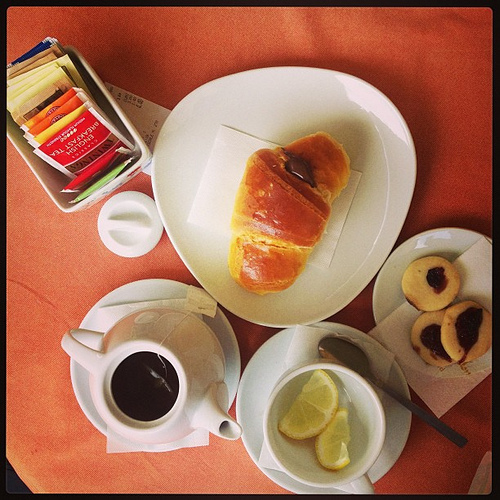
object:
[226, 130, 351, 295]
crossant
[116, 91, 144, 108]
black lettering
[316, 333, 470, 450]
metal spoon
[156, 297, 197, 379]
bag string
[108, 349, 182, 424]
brewed drink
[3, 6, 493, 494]
ground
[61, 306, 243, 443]
kettle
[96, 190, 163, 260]
top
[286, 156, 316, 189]
chocolate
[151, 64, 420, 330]
plate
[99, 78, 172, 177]
bill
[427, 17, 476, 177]
table cloth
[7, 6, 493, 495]
table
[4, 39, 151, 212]
container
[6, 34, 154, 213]
bags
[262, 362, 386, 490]
bowel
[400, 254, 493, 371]
cookies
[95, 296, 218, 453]
napkin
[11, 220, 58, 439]
tablecloth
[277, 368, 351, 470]
lemon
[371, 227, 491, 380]
plate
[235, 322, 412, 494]
plate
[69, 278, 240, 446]
plate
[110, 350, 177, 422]
drink